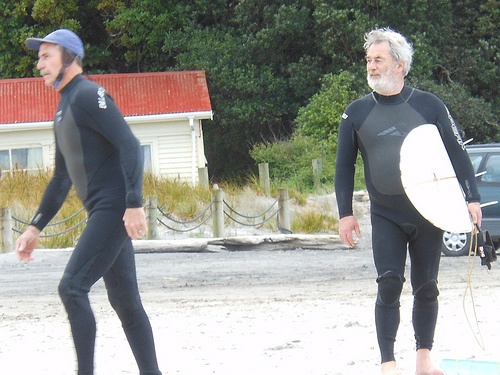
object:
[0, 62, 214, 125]
roof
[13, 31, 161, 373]
man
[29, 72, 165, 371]
swim suit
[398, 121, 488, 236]
surf board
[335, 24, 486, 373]
man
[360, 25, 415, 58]
hair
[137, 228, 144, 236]
ring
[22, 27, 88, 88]
hat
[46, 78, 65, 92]
chin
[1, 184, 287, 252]
fence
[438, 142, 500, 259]
vehicle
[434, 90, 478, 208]
arm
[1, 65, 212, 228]
house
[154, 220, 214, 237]
links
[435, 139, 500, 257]
car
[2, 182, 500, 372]
beach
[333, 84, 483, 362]
wet suit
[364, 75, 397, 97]
beard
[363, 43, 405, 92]
face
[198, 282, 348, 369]
sand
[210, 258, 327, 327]
ground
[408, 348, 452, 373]
feet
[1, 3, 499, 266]
background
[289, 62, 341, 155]
trees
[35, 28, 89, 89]
head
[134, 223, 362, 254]
wood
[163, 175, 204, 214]
grass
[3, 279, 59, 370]
road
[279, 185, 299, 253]
poles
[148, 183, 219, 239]
barriers